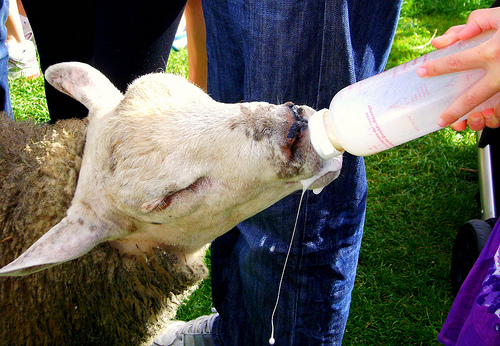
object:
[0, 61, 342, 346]
sheep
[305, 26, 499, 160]
bottle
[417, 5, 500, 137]
person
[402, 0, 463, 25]
grass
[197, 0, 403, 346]
jeans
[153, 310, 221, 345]
shoe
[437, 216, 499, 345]
cloth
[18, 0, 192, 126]
pants